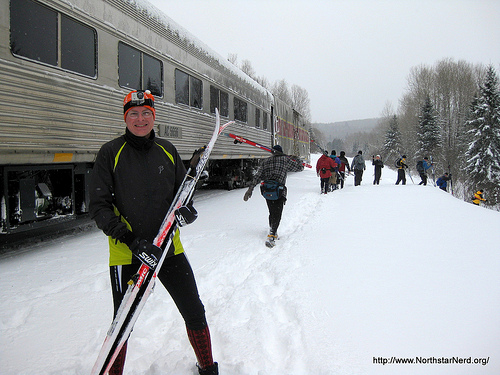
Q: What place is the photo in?
A: It is at the path.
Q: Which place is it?
A: It is a path.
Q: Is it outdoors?
A: Yes, it is outdoors.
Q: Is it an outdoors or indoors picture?
A: It is outdoors.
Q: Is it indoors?
A: No, it is outdoors.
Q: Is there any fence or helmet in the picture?
A: No, there are no helmets or fences.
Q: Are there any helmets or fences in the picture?
A: No, there are no helmets or fences.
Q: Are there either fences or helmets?
A: No, there are no helmets or fences.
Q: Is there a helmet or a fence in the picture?
A: No, there are no helmets or fences.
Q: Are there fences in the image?
A: No, there are no fences.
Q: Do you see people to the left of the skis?
A: No, the person is to the right of the skis.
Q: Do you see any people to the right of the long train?
A: Yes, there is a person to the right of the train.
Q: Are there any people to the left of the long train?
A: No, the person is to the right of the train.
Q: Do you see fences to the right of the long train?
A: No, there is a person to the right of the train.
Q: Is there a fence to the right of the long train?
A: No, there is a person to the right of the train.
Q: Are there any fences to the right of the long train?
A: No, there is a person to the right of the train.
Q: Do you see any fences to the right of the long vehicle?
A: No, there is a person to the right of the train.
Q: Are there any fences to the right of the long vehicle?
A: No, there is a person to the right of the train.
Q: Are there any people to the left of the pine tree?
A: Yes, there is a person to the left of the pine tree.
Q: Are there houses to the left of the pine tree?
A: No, there is a person to the left of the pine tree.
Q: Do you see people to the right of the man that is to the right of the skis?
A: Yes, there is a person to the right of the man.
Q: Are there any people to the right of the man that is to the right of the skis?
A: Yes, there is a person to the right of the man.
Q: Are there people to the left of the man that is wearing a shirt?
A: No, the person is to the right of the man.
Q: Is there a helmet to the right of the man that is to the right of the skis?
A: No, there is a person to the right of the man.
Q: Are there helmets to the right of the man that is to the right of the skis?
A: No, there is a person to the right of the man.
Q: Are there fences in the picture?
A: No, there are no fences.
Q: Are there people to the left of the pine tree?
A: Yes, there is a person to the left of the pine tree.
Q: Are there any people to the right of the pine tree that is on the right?
A: No, the person is to the left of the pine.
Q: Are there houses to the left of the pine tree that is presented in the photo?
A: No, there is a person to the left of the pine tree.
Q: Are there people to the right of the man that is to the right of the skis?
A: Yes, there is a person to the right of the man.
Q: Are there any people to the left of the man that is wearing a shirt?
A: No, the person is to the right of the man.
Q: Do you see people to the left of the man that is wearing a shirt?
A: No, the person is to the right of the man.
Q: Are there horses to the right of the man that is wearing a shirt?
A: No, there is a person to the right of the man.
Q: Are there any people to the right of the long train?
A: Yes, there is a person to the right of the train.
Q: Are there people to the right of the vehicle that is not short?
A: Yes, there is a person to the right of the train.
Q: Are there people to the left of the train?
A: No, the person is to the right of the train.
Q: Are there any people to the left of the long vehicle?
A: No, the person is to the right of the train.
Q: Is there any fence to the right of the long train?
A: No, there is a person to the right of the train.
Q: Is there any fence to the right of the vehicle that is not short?
A: No, there is a person to the right of the train.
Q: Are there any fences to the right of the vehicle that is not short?
A: No, there is a person to the right of the train.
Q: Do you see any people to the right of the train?
A: Yes, there is a person to the right of the train.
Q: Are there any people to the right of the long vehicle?
A: Yes, there is a person to the right of the train.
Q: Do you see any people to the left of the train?
A: No, the person is to the right of the train.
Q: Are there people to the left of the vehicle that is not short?
A: No, the person is to the right of the train.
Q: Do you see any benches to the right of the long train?
A: No, there is a person to the right of the train.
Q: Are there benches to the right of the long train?
A: No, there is a person to the right of the train.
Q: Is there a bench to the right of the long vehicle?
A: No, there is a person to the right of the train.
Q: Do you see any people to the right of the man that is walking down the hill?
A: Yes, there is a person to the right of the man.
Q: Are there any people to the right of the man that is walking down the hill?
A: Yes, there is a person to the right of the man.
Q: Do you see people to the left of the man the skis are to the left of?
A: No, the person is to the right of the man.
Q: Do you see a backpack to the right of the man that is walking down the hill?
A: No, there is a person to the right of the man.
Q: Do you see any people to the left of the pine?
A: Yes, there is a person to the left of the pine.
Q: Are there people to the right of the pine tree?
A: No, the person is to the left of the pine tree.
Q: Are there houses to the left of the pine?
A: No, there is a person to the left of the pine.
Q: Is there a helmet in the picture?
A: No, there are no helmets.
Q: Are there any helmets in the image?
A: No, there are no helmets.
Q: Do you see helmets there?
A: No, there are no helmets.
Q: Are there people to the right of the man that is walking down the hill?
A: Yes, there is a person to the right of the man.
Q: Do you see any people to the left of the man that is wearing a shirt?
A: No, the person is to the right of the man.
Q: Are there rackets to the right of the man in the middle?
A: No, there is a person to the right of the man.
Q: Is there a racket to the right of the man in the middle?
A: No, there is a person to the right of the man.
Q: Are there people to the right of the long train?
A: Yes, there is a person to the right of the train.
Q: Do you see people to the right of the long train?
A: Yes, there is a person to the right of the train.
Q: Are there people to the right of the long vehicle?
A: Yes, there is a person to the right of the train.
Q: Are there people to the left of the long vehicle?
A: No, the person is to the right of the train.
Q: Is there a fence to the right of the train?
A: No, there is a person to the right of the train.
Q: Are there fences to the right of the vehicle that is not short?
A: No, there is a person to the right of the train.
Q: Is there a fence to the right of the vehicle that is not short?
A: No, there is a person to the right of the train.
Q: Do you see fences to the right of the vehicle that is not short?
A: No, there is a person to the right of the train.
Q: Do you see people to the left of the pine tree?
A: Yes, there is a person to the left of the pine tree.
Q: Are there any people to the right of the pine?
A: No, the person is to the left of the pine.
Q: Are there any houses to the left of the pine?
A: No, there is a person to the left of the pine.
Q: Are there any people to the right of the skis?
A: Yes, there is a person to the right of the skis.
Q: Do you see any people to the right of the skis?
A: Yes, there is a person to the right of the skis.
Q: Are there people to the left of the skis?
A: No, the person is to the right of the skis.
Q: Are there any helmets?
A: No, there are no helmets.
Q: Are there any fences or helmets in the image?
A: No, there are no helmets or fences.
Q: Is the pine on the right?
A: Yes, the pine is on the right of the image.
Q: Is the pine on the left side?
A: No, the pine is on the right of the image.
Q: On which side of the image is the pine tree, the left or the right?
A: The pine tree is on the right of the image.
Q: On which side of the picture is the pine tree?
A: The pine tree is on the right of the image.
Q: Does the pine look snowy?
A: Yes, the pine is snowy.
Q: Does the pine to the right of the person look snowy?
A: Yes, the pine is snowy.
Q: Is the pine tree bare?
A: No, the pine tree is snowy.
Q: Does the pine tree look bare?
A: No, the pine tree is snowy.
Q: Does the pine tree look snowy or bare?
A: The pine tree is snowy.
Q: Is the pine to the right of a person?
A: Yes, the pine is to the right of a person.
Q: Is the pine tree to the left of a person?
A: No, the pine tree is to the right of a person.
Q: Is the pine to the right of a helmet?
A: No, the pine is to the right of a person.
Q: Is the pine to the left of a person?
A: No, the pine is to the right of a person.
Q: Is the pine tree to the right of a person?
A: Yes, the pine tree is to the right of a person.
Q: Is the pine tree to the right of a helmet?
A: No, the pine tree is to the right of a person.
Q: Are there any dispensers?
A: No, there are no dispensers.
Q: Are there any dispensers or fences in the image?
A: No, there are no dispensers or fences.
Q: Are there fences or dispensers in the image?
A: No, there are no dispensers or fences.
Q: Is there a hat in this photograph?
A: Yes, there is a hat.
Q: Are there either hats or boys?
A: Yes, there is a hat.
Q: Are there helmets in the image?
A: No, there are no helmets.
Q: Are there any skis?
A: Yes, there are skis.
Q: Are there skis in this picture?
A: Yes, there are skis.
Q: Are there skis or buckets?
A: Yes, there are skis.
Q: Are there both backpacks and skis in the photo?
A: No, there are skis but no backpacks.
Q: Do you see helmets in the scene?
A: No, there are no helmets.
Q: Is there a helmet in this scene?
A: No, there are no helmets.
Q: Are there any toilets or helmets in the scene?
A: No, there are no helmets or toilets.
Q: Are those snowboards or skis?
A: Those are skis.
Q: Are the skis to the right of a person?
A: No, the skis are to the left of a person.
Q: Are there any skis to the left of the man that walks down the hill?
A: Yes, there are skis to the left of the man.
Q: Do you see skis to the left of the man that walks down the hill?
A: Yes, there are skis to the left of the man.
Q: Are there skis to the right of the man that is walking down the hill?
A: No, the skis are to the left of the man.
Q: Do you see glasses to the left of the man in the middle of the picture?
A: No, there are skis to the left of the man.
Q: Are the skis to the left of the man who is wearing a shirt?
A: Yes, the skis are to the left of the man.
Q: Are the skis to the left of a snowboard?
A: No, the skis are to the left of the man.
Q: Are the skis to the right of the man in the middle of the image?
A: No, the skis are to the left of the man.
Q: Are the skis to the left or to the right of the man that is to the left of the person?
A: The skis are to the left of the man.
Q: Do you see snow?
A: Yes, there is snow.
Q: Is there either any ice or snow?
A: Yes, there is snow.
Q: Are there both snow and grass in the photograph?
A: No, there is snow but no grass.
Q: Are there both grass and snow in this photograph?
A: No, there is snow but no grass.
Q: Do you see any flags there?
A: No, there are no flags.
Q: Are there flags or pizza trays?
A: No, there are no flags or pizza trays.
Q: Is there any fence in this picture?
A: No, there are no fences.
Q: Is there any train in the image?
A: Yes, there is a train.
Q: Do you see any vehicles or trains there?
A: Yes, there is a train.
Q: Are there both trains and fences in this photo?
A: No, there is a train but no fences.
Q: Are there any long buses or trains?
A: Yes, there is a long train.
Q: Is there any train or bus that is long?
A: Yes, the train is long.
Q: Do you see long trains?
A: Yes, there is a long train.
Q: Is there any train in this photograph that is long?
A: Yes, there is a train that is long.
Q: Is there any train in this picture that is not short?
A: Yes, there is a long train.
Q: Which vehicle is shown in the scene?
A: The vehicle is a train.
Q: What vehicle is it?
A: The vehicle is a train.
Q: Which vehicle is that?
A: This is a train.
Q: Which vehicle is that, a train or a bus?
A: This is a train.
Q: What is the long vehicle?
A: The vehicle is a train.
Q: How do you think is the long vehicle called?
A: The vehicle is a train.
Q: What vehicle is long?
A: The vehicle is a train.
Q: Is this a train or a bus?
A: This is a train.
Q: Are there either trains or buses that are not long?
A: No, there is a train but it is long.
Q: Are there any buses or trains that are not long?
A: No, there is a train but it is long.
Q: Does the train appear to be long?
A: Yes, the train is long.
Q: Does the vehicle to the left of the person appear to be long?
A: Yes, the train is long.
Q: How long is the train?
A: The train is long.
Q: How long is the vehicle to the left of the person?
A: The train is long.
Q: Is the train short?
A: No, the train is long.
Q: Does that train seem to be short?
A: No, the train is long.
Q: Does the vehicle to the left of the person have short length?
A: No, the train is long.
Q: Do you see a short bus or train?
A: No, there is a train but it is long.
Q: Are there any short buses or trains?
A: No, there is a train but it is long.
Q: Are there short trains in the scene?
A: No, there is a train but it is long.